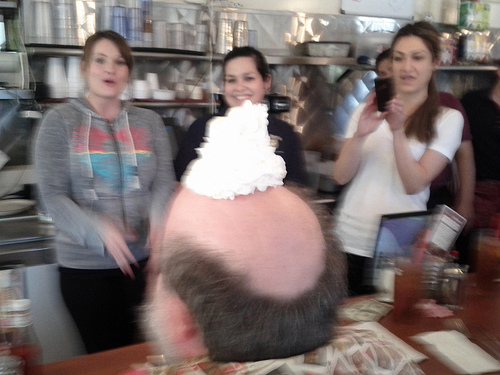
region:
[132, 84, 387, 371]
man with whipped cream on his head.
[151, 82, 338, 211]
White whipped cream.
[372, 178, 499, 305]
Stuff on the table.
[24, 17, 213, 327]
Girl with a gray hoodie.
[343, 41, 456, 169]
Woman holding a phone.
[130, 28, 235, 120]
Cups on the shelf.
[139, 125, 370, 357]
Man who is bald.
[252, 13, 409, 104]
Shelves in the background.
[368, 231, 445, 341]
Drink on the table.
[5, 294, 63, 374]
Bottle on the table.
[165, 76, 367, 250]
Man with whipped cream on his head.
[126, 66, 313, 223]
Man with white whipped cream on his head.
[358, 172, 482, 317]
Things on the table.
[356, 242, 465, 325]
Glass on the table.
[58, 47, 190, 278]
Strings on the gray hoodie.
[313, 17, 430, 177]
Woman with a phone.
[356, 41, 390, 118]
Woman with a black phone.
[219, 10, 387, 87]
Metal shelf in the background.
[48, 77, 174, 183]
Heart on the girl's shirt.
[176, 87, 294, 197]
shaving cream on top of head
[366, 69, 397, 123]
phone in girls hand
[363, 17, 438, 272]
girl taking photo with phone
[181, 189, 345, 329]
bald head of man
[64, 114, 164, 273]
grey hoodie on girl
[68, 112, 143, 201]
strings for hoodie top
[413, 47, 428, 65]
left eye of girl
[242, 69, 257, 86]
left eye of girl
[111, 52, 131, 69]
left eye of girl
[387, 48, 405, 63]
right eye of girl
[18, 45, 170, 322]
Blurriness from movement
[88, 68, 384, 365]
Whipped cream on bald head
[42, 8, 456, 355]
Girls laughing at the goofy man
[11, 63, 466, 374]
Man at a diner with whipped cream on his head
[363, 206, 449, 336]
Drink with a straw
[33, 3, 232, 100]
Cups on the shelves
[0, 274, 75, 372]
Bottle of ketchup on the counter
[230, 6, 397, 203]
Lots of reflective chrome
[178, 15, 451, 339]
Girl photographs the scene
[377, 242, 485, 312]
Condiments on the counter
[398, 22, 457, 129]
Person has brown hair.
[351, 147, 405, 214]
Person wearing white shirt.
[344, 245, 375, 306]
Person wearing dark pants.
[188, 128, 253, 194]
White cream on person's head.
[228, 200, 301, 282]
Person has a bald head.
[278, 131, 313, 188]
Person wearing black shirt.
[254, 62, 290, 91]
Person has dark hair.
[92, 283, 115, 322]
Person wearing dark pants.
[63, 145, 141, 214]
Person wearing gray shirt.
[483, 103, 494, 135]
Person wearing black shirt.